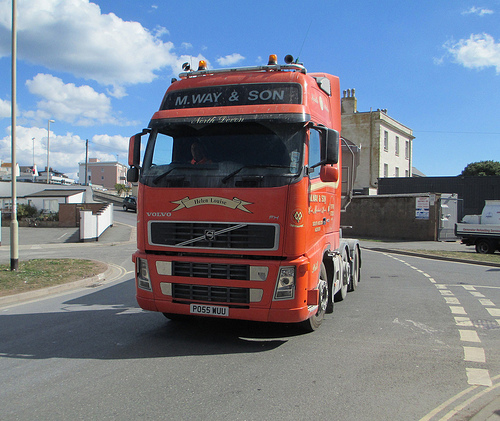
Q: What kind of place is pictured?
A: It is a road.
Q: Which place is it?
A: It is a road.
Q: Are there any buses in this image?
A: No, there are no buses.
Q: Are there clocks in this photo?
A: No, there are no clocks.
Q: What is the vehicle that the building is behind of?
A: The vehicle is a truck.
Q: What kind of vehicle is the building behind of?
A: The building is behind the truck.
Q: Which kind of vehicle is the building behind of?
A: The building is behind the truck.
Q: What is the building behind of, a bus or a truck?
A: The building is behind a truck.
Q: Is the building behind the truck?
A: Yes, the building is behind the truck.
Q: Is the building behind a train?
A: No, the building is behind the truck.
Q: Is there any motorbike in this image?
A: No, there are no motorcycles.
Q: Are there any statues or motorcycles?
A: No, there are no motorcycles or statues.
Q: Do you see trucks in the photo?
A: Yes, there is a truck.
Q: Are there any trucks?
A: Yes, there is a truck.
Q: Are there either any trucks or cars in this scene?
A: Yes, there is a truck.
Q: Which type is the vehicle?
A: The vehicle is a truck.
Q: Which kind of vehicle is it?
A: The vehicle is a truck.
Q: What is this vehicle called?
A: This is a truck.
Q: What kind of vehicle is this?
A: This is a truck.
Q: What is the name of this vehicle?
A: This is a truck.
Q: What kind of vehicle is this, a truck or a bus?
A: This is a truck.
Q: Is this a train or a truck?
A: This is a truck.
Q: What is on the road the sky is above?
A: The truck is on the road.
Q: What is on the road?
A: The truck is on the road.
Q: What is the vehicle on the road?
A: The vehicle is a truck.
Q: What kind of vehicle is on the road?
A: The vehicle is a truck.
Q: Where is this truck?
A: The truck is on the road.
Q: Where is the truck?
A: The truck is on the road.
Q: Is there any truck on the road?
A: Yes, there is a truck on the road.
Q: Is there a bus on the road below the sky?
A: No, there is a truck on the road.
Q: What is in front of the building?
A: The truck is in front of the building.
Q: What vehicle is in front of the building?
A: The vehicle is a truck.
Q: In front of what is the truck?
A: The truck is in front of the building.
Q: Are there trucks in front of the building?
A: Yes, there is a truck in front of the building.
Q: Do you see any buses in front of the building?
A: No, there is a truck in front of the building.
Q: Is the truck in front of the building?
A: Yes, the truck is in front of the building.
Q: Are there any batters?
A: No, there are no batters.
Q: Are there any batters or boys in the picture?
A: No, there are no batters or boys.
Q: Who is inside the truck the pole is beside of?
A: The man is inside the truck.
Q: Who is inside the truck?
A: The man is inside the truck.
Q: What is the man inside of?
A: The man is inside the truck.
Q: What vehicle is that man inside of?
A: The man is inside the truck.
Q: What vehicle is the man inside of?
A: The man is inside the truck.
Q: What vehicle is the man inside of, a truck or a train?
A: The man is inside a truck.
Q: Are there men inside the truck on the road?
A: Yes, there is a man inside the truck.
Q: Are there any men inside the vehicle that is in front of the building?
A: Yes, there is a man inside the truck.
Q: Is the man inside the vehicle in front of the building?
A: Yes, the man is inside the truck.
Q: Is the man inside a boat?
A: No, the man is inside the truck.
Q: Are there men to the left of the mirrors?
A: Yes, there is a man to the left of the mirrors.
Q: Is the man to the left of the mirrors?
A: Yes, the man is to the left of the mirrors.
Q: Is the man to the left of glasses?
A: No, the man is to the left of the mirrors.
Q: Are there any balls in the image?
A: No, there are no balls.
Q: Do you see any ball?
A: No, there are no balls.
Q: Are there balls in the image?
A: No, there are no balls.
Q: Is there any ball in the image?
A: No, there are no balls.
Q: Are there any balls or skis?
A: No, there are no balls or skis.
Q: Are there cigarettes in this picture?
A: No, there are no cigarettes.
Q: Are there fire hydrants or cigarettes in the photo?
A: No, there are no cigarettes or fire hydrants.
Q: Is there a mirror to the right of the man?
A: Yes, there are mirrors to the right of the man.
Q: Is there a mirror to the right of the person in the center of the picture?
A: Yes, there are mirrors to the right of the man.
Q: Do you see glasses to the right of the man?
A: No, there are mirrors to the right of the man.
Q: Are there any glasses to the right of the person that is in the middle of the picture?
A: No, there are mirrors to the right of the man.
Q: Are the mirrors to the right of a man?
A: Yes, the mirrors are to the right of a man.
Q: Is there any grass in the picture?
A: Yes, there is grass.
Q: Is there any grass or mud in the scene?
A: Yes, there is grass.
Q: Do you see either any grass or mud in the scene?
A: Yes, there is grass.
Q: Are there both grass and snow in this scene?
A: No, there is grass but no snow.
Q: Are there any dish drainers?
A: No, there are no dish drainers.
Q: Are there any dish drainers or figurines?
A: No, there are no dish drainers or figurines.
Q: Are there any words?
A: Yes, there are words.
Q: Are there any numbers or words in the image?
A: Yes, there are words.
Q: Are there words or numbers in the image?
A: Yes, there are words.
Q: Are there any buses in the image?
A: No, there are no buses.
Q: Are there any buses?
A: No, there are no buses.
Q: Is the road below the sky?
A: Yes, the road is below the sky.